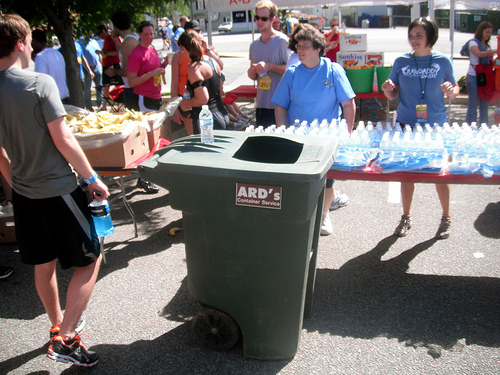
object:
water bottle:
[199, 105, 214, 145]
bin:
[136, 129, 337, 359]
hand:
[381, 79, 396, 92]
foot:
[436, 217, 452, 239]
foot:
[395, 215, 413, 237]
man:
[0, 14, 113, 368]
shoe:
[46, 331, 100, 367]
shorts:
[11, 187, 102, 270]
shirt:
[0, 69, 81, 200]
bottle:
[88, 191, 115, 238]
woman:
[382, 17, 460, 239]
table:
[244, 118, 499, 179]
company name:
[235, 182, 282, 210]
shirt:
[387, 49, 456, 129]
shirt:
[270, 56, 356, 235]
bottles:
[242, 117, 500, 174]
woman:
[126, 20, 169, 112]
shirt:
[128, 44, 164, 100]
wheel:
[191, 305, 242, 351]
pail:
[345, 64, 374, 94]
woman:
[271, 23, 356, 236]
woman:
[177, 28, 230, 135]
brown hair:
[177, 29, 204, 66]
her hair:
[408, 15, 439, 51]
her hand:
[381, 79, 396, 92]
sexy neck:
[301, 54, 320, 69]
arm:
[185, 65, 210, 107]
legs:
[395, 180, 450, 239]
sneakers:
[435, 215, 452, 239]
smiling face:
[408, 24, 427, 51]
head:
[0, 14, 33, 70]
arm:
[34, 79, 99, 185]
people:
[247, 0, 295, 127]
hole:
[232, 136, 304, 164]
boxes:
[69, 116, 150, 169]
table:
[96, 166, 143, 238]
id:
[413, 52, 433, 123]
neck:
[412, 48, 433, 57]